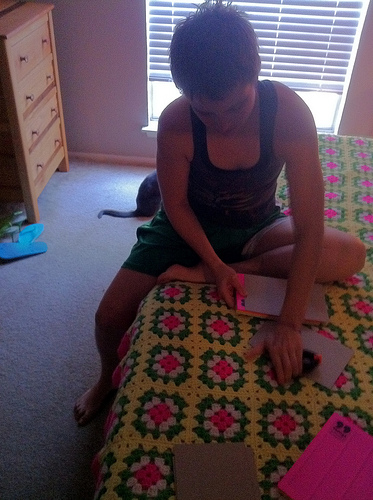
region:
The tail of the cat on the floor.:
[93, 200, 142, 222]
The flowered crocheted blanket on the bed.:
[153, 271, 341, 499]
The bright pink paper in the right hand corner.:
[282, 401, 372, 493]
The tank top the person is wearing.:
[175, 82, 279, 206]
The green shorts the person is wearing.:
[119, 196, 281, 278]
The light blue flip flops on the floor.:
[5, 222, 49, 265]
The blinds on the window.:
[148, 3, 346, 93]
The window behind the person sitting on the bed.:
[147, 4, 347, 140]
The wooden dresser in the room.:
[2, 7, 91, 211]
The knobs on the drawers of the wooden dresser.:
[14, 44, 85, 175]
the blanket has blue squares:
[154, 349, 257, 423]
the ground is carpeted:
[23, 361, 53, 491]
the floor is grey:
[21, 353, 59, 479]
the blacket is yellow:
[144, 365, 238, 419]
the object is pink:
[309, 426, 371, 499]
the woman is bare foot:
[159, 38, 348, 277]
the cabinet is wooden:
[11, 26, 71, 190]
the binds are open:
[294, 10, 335, 81]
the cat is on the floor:
[129, 169, 162, 214]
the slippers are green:
[17, 218, 59, 267]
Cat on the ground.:
[95, 168, 163, 221]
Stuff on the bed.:
[158, 387, 371, 494]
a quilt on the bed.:
[137, 380, 253, 438]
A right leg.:
[68, 250, 157, 444]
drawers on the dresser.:
[5, 36, 77, 200]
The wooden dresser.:
[1, 3, 76, 222]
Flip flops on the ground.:
[0, 213, 49, 260]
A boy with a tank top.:
[161, 69, 287, 267]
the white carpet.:
[20, 290, 62, 444]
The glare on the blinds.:
[149, 5, 351, 98]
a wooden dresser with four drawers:
[10, 13, 62, 228]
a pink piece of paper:
[314, 407, 364, 498]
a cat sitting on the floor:
[94, 165, 163, 234]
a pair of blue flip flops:
[0, 207, 41, 271]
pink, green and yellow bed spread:
[134, 326, 234, 430]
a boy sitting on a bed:
[128, 19, 303, 288]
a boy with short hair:
[161, 23, 279, 141]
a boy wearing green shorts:
[120, 13, 273, 306]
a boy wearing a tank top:
[152, 29, 283, 232]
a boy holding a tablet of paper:
[157, 65, 305, 327]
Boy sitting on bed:
[129, 15, 362, 304]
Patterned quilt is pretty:
[154, 338, 282, 453]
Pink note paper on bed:
[276, 427, 371, 480]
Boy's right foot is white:
[75, 375, 114, 418]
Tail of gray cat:
[89, 202, 137, 226]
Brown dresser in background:
[3, 10, 78, 192]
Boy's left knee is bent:
[332, 209, 363, 276]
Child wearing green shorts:
[129, 217, 276, 270]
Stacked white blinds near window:
[265, 4, 348, 84]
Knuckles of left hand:
[261, 345, 316, 372]